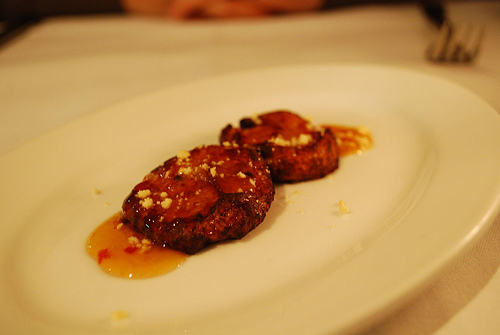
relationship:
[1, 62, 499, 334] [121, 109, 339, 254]
plate has steak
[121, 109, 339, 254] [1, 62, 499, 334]
steak on plate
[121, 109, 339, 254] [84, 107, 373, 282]
steak has sauce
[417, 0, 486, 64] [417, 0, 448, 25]
fork has handle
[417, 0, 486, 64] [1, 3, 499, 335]
fork on table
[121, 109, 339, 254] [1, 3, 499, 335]
steak on table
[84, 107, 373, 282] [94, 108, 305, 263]
sauce has chili flakes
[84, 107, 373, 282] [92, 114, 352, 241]
sauce has cheese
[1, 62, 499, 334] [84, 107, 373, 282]
plate has sauce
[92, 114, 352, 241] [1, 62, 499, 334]
cheese on plate